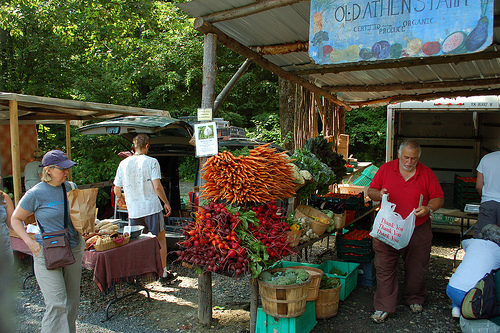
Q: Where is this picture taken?
A: A market.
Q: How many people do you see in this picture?
A: Five.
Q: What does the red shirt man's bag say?
A: Thank you.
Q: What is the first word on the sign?
A: Old.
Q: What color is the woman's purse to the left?
A: Brown.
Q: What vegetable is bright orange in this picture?
A: Carrots.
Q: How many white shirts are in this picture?
A: Three.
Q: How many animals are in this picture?
A: None.